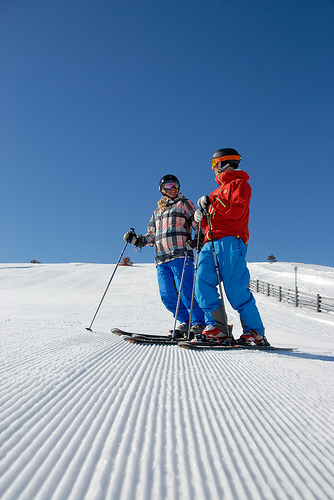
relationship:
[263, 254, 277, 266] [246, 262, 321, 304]
tree on hill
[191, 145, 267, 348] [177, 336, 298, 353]
person wearing skis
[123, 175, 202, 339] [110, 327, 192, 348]
person wearing skis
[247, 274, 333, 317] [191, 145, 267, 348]
fence behind person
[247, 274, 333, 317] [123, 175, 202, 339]
fence behind person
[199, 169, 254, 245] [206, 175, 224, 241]
jacket has zipper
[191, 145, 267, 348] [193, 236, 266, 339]
person wearing ski pants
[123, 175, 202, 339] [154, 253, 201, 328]
person wearing ski pants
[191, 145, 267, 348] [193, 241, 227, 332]
person has leg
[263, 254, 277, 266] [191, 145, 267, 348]
tree behind person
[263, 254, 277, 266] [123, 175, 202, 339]
tree behind person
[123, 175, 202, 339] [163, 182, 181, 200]
person has face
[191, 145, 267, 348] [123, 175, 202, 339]
person talking to person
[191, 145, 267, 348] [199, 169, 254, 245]
person in jacket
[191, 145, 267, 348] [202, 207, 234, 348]
person holding ski pole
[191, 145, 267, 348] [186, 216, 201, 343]
person holding ski pole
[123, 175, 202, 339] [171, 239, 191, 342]
person holding ski pole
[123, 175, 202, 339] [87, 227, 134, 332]
person holding ski pole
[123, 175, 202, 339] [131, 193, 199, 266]
person in jacket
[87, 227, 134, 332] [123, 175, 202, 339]
ski pole held by person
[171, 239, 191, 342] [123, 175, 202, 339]
ski pole held by person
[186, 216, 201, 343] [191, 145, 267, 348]
ski pole held by person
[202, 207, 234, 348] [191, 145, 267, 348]
ski pole held by person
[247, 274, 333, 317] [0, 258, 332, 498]
fence in snow